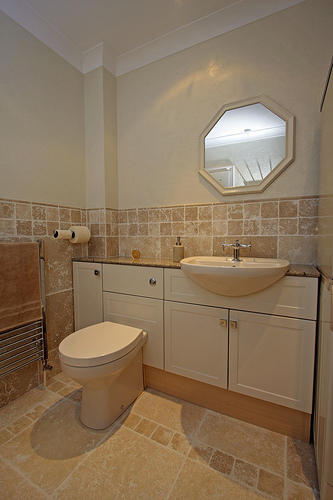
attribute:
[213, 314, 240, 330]
cupboard handles — square shaped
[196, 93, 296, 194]
mirror — cream, oblong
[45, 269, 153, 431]
toilet — cream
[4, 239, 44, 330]
towel — rust colored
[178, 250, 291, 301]
sink — oval shaped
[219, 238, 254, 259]
faucet — chrome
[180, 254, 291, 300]
sink — cream, hanging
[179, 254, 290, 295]
sink — brown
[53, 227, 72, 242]
toilet paper — small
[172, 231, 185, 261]
soap dispenser — small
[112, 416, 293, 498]
lines — white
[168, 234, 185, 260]
lotion dispenser — pump top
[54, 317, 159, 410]
toilet bowl — white, porcelain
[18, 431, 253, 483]
flooring — light brown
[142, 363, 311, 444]
baseboard — wooden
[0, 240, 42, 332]
towel — brown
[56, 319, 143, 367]
lid — white, plastic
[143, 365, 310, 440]
base — brown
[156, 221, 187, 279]
soap holder — brown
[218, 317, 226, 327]
handle — brown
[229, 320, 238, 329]
handle — brown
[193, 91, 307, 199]
mirror — octagonal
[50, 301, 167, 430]
toilet — beige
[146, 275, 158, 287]
flush valve — chrome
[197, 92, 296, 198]
mirror frame — octagonal shaped